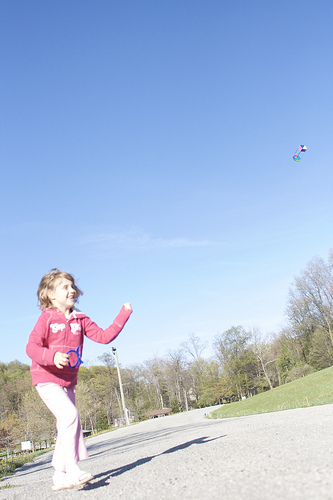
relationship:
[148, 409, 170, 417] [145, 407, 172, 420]
roof on a house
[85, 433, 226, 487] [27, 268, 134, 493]
shadow of girl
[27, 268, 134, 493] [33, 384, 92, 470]
girl wearing pants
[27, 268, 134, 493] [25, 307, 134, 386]
girl wearing jacket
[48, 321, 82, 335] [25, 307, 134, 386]
letters on jacket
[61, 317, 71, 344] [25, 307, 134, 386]
zipper on jacket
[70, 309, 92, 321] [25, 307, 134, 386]
hood on jacket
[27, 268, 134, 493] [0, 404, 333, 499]
girl on road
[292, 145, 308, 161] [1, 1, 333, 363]
kite in sky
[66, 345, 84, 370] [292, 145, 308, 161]
handle to kite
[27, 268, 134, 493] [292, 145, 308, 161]
girl flying kite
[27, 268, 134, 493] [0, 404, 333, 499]
girl running on road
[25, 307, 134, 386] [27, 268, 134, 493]
jacket on girl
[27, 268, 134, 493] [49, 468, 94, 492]
girl has shoes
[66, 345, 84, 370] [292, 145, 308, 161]
handle of kite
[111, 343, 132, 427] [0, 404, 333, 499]
lamppost next to road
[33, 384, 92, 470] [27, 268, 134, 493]
pants on girl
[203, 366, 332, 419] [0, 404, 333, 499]
grass beside road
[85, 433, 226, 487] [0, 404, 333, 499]
shadow on road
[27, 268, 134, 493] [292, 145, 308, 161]
girl holding kite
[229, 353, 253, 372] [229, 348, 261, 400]
leaves on tree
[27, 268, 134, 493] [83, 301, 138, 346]
girl has arm